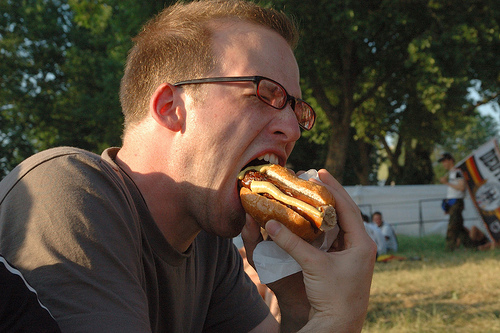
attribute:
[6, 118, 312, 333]
shirt — brown, here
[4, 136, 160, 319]
sleeve — here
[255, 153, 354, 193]
bread — here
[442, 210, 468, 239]
trouser — here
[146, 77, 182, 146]
ear — here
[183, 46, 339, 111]
spectacles — here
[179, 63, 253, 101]
fram — black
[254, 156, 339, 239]
hot dog — here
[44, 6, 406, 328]
man — biting, here, eating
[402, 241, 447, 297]
grass — here, green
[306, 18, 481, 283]
tree — here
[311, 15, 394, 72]
leaves — green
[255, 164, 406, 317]
hand — here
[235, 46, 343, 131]
sunglasses — here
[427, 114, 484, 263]
man — standing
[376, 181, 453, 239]
wall — white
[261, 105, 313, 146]
nose — here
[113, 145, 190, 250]
neck — here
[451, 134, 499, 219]
flag — held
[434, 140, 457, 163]
cap — worn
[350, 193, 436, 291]
people — sitting